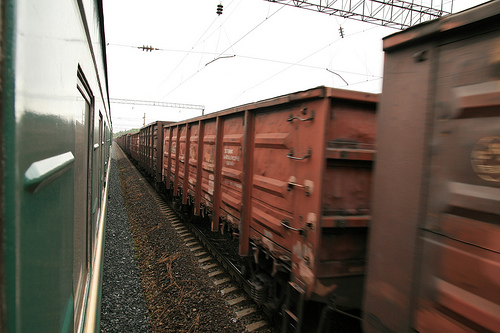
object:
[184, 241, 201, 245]
crosstie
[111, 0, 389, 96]
power lines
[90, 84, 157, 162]
building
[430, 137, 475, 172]
ground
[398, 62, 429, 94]
ground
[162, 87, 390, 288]
goods carrier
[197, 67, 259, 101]
ground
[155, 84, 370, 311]
train car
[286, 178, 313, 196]
rung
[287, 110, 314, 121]
handle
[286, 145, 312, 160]
handle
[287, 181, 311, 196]
handle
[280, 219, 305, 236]
handle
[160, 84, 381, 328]
cargo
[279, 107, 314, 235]
ladder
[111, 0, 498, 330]
car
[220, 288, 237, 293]
wooden crosstie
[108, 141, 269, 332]
rails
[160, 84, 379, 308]
cargo freight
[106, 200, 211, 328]
ground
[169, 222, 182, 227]
wooden crosstie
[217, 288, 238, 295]
wooden crosstie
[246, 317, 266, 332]
wooden crosstie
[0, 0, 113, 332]
train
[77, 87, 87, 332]
window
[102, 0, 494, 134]
sky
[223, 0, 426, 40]
seperaters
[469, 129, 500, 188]
logo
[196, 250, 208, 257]
crosstie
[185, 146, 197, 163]
circle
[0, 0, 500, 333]
picture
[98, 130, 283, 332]
gravel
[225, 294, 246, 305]
crosstie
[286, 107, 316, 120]
rung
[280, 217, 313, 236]
rung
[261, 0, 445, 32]
rods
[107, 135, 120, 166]
white circle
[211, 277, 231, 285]
crosstie